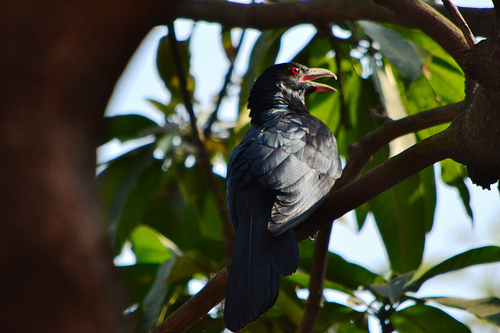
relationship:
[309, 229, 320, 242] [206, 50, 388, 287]
foot of bird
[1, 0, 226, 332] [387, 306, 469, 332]
tree has green leaves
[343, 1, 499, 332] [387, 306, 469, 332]
tree has leaves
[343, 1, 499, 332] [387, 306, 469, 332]
tree has green leaves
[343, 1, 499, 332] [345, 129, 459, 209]
tree has branches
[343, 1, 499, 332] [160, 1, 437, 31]
tree has  many branches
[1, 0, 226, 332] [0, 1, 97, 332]
tree has large trunk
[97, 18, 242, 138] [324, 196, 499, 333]
blue sky through leaves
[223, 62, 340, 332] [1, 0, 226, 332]
bird in tree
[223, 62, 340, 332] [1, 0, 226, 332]
black bird in a tree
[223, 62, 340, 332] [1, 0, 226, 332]
bird in a tree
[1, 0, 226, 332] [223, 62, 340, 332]
tree has a bird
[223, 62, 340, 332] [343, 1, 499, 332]
bird in a green tree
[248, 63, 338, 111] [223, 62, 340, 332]
head of a bird of prey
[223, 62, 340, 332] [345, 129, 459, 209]
bird on a branch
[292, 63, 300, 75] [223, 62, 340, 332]
eye of bird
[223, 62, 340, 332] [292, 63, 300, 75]
birds eye red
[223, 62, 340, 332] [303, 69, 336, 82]
bird has a beak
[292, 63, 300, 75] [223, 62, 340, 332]
red eye on bird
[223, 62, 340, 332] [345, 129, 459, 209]
bird on tree branch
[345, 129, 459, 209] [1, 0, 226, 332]
brown branch on a tree